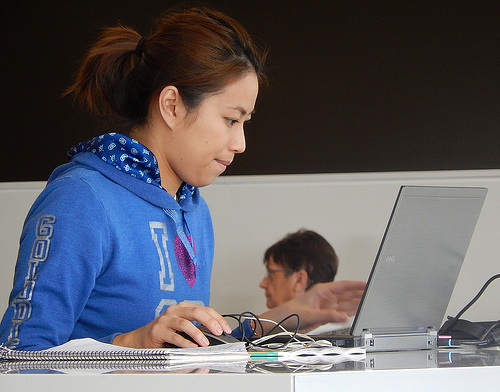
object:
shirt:
[0, 130, 216, 355]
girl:
[0, 0, 270, 356]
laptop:
[235, 184, 490, 355]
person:
[259, 227, 339, 311]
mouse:
[161, 324, 248, 351]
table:
[283, 359, 500, 390]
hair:
[60, 6, 272, 126]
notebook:
[0, 336, 253, 362]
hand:
[115, 299, 233, 352]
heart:
[172, 232, 199, 288]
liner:
[61, 129, 166, 191]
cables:
[281, 311, 307, 326]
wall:
[280, 0, 500, 163]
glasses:
[265, 266, 286, 279]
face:
[186, 67, 260, 191]